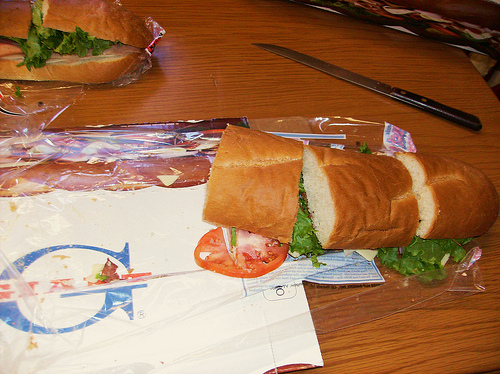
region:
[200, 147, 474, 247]
A bun in the picture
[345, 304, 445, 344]
A table in the photo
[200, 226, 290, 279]
a slice of tomato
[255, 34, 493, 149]
A knife in the photo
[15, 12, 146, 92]
A burger in the photo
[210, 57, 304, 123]
A table in the photo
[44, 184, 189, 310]
A wrapper on the table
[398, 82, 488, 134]
A handle on the knife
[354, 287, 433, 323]
Plastic bag on the table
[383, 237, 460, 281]
Green vegetables on the burger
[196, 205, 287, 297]
orange tomato under sub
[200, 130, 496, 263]
bread has been cut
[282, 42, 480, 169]
black knife on table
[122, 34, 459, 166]
table is dark brown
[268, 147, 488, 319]
green lettuce on sub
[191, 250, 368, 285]
blue and white paper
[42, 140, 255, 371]
blue and white box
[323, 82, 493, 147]
black handle on knife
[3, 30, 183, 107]
second sub in rear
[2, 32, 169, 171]
plastic wrap under sub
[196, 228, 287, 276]
round slice of tomato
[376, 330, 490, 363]
brown table top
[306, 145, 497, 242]
slices of bread loaf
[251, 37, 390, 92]
sharp blade of knife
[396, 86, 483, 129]
Black handle of knife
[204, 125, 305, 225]
Brown slice bread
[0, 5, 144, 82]
green leafy stuffing between bread slice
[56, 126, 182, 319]
plastic cover lying over table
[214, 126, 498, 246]
three slices of bread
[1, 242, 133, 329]
Alphabet G written in blue color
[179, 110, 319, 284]
slice of sandwich on the table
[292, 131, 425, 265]
slice of sandwich on the table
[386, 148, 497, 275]
slice of sandwich on the table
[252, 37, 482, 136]
knife with a blade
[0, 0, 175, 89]
slice of sandwich on the table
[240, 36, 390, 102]
blade of a knife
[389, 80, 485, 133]
handle of a knife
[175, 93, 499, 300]
large sandwich on the table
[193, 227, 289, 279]
slice of tomato on the table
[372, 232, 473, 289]
leaves of green lettuce